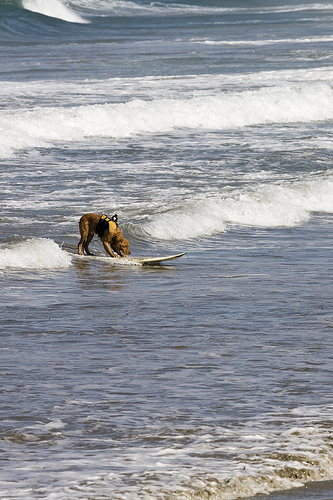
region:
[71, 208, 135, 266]
Dog riding a surfboard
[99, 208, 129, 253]
Dog is wearing a life vest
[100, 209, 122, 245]
Life vest is yellow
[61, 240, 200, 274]
Surfboard is white on top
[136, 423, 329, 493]
Water is very frothy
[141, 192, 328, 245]
Waves are white and choppy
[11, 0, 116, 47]
High wave is coming in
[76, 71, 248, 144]
White water is rough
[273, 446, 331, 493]
Sand and pebbles in the surf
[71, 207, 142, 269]
Dog is not happy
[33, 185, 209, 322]
the dog is surfing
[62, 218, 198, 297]
the surfboard is white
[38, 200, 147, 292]
the dog is brown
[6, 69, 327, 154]
the wave is white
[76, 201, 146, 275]
the life vest is yellow and black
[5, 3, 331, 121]
the water is blue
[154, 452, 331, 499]
the sand is brown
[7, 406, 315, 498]
the water is foamy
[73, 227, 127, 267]
the dog has four legs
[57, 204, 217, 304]
the dog is standing on a surfboard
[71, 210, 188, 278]
a brown dog on a surfboard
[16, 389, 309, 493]
brown and white ripples in ocean water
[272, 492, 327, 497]
wet brown sand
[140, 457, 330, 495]
the area where the ocean meets the sand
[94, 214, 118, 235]
a black and yellow safety jacket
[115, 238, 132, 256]
a dog's head tilted downward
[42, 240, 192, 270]
a white surfboard in the ocean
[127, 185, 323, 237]
a small white ocean wave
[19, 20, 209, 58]
an area of calm blue ocean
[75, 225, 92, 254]
the back legs of a brown dog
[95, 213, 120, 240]
Life vest on a dog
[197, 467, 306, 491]
Small wave crashing on a beach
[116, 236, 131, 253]
Dog with its face near a surfboard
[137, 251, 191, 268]
Tip of a white surfboard out of the water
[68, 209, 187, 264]
Dog surfing on a board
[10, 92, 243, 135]
White wave tip in the ocean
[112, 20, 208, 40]
Blue water in the ocean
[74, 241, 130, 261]
Four dog paws on a surfboard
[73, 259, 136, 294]
Reflection of a dog in the ocean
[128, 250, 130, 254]
Black nose of a golden dog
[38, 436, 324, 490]
brown and white rippling ocean water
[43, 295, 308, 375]
blue rippled ocean water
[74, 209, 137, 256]
a brown dog on a surfboard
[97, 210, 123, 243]
a yellow safety jacket on a dog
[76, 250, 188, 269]
a white surfboard in the water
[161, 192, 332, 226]
small white ocean wave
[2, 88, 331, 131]
a long line of white ocean water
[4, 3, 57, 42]
a blue ocean wave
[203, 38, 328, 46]
a thin white line in the water